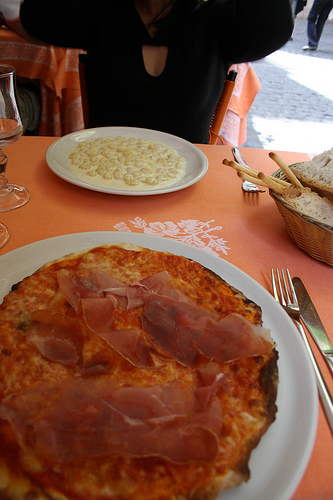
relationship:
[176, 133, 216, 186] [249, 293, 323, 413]
plate in bowl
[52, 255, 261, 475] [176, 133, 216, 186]
pizza on plate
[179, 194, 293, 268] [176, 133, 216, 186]
table on plate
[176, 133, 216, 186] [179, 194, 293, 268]
plate on table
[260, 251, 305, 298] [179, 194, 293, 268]
fork on table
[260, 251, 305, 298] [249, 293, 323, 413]
fork near bowl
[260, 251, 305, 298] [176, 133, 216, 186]
fork by plate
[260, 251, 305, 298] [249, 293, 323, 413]
fork by bowl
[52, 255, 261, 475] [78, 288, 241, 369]
pizza with ham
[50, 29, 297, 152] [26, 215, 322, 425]
chair at table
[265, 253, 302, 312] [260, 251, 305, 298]
tines of fork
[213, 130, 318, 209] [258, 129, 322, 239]
bread in basket